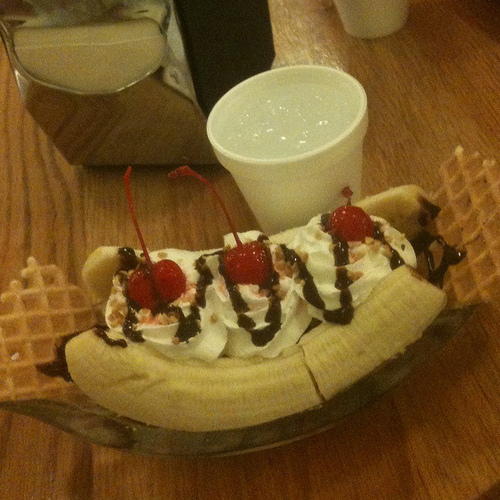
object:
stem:
[123, 164, 155, 269]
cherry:
[123, 163, 187, 308]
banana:
[64, 262, 448, 430]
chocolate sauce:
[33, 194, 466, 382]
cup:
[204, 62, 368, 237]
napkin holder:
[0, 0, 275, 169]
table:
[0, 0, 499, 499]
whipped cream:
[103, 212, 417, 362]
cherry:
[165, 162, 274, 285]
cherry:
[326, 184, 374, 243]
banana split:
[0, 145, 499, 457]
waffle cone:
[0, 254, 117, 411]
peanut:
[274, 287, 287, 300]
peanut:
[211, 312, 219, 323]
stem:
[167, 163, 243, 248]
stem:
[340, 186, 353, 206]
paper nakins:
[6, 19, 164, 97]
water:
[212, 72, 360, 164]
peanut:
[172, 336, 181, 345]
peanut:
[364, 235, 375, 245]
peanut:
[346, 269, 365, 282]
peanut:
[157, 251, 169, 260]